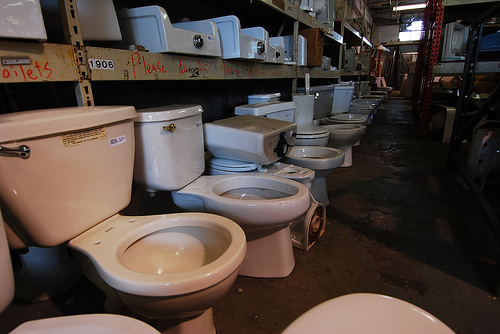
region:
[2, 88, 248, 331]
pink and white toilet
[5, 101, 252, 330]
white and pink porcelain toilet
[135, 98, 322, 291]
white toilet without lid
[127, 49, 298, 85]
red lettering on metal shelf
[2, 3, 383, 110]
metal shelving holding merchandise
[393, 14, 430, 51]
high exterior window on wall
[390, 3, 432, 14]
hanging fluorescent light bulb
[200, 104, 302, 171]
toilet tank laying on it's side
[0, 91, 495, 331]
dirty concrete warehouse floor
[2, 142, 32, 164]
silver toilet flush handle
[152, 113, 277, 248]
the toilet is white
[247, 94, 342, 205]
the toilet is white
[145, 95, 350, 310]
the toilet is white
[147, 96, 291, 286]
the toilet is made of marble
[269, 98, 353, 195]
the toilet is made of marble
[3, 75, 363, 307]
A long row of toilette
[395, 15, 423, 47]
A window with light coming through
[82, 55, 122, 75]
The numbers 1906 on the shelf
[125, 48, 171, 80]
The word please on the shelf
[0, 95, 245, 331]
A toilet with no seat or lid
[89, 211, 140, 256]
Holes to secure a toilet seat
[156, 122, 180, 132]
The lever on the toilet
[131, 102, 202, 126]
The lid on the back of the toilet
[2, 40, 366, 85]
A shelf above the toilets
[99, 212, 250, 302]
the toilet bowl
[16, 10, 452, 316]
this is a warehouse of toilets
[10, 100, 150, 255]
this is a toilet tank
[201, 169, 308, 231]
this is the toilet bowl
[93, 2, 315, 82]
these toilet parts are stored on a shelf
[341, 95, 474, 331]
the floor is made up of concrete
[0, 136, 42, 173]
the toilets flushing handle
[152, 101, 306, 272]
this toilet is white in color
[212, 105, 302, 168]
this is a toilet tank resting on the bottom portion of the toilet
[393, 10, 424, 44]
this is a window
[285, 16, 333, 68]
a card board box is on the shelf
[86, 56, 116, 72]
The number 1906 on a shelf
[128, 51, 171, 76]
The word please written in orange letters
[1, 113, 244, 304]
A toilet in a warehouse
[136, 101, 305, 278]
A toilet in a warehouse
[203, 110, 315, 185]
A toilet in a warehouse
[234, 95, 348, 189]
A toilet in a warehouse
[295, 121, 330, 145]
A toilet bowl in a warehouse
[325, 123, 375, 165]
A toilet bowl in a warehouse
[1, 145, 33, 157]
A silver handle on a toilet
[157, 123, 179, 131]
A gold handle on a toilet